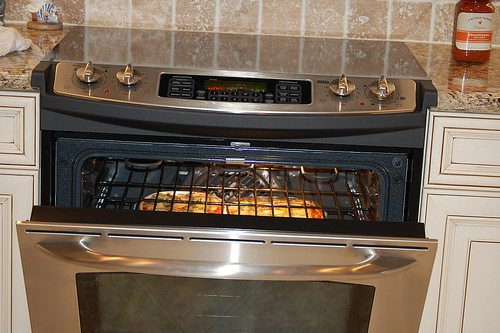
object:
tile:
[132, 0, 172, 29]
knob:
[77, 61, 103, 83]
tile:
[348, 0, 386, 38]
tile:
[387, 0, 431, 41]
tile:
[84, 0, 131, 26]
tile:
[215, 0, 259, 33]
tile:
[306, 1, 345, 39]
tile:
[172, 1, 217, 31]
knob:
[369, 74, 396, 99]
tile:
[258, 1, 302, 36]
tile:
[391, 0, 435, 43]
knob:
[329, 73, 355, 97]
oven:
[16, 25, 439, 333]